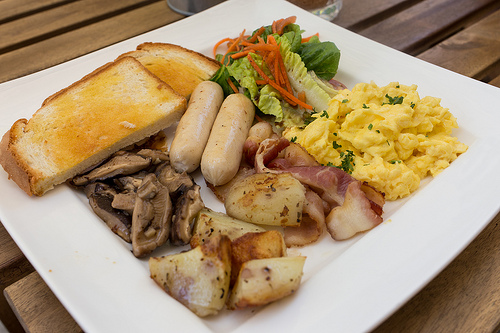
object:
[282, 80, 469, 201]
egg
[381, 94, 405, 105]
herbs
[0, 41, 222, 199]
toast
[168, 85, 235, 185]
links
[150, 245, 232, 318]
potato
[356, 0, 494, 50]
wood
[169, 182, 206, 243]
mushroom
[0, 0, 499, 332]
dish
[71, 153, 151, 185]
muchrooms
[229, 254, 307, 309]
potato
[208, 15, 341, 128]
salad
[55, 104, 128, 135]
butter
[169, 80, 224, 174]
sausage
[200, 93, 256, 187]
sausage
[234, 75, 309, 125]
wall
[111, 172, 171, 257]
mushroom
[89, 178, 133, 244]
mushroom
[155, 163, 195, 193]
mushroom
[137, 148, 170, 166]
mushroom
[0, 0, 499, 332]
table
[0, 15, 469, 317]
food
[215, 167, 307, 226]
potato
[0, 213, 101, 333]
edge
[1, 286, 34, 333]
edge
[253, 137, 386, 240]
bacon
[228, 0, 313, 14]
corner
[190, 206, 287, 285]
potato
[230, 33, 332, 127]
vegetables